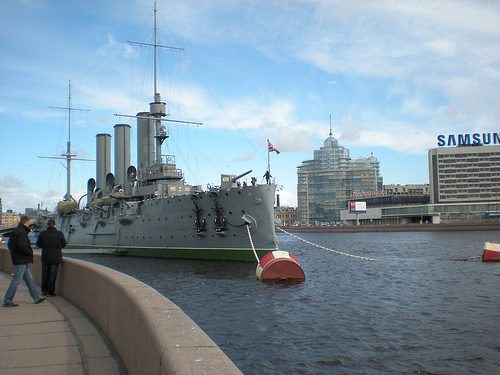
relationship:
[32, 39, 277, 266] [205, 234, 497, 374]
ship in water.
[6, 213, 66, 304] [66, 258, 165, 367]
men near wall.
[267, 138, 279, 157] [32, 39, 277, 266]
flag on ship.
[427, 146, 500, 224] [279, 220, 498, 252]
building near waterfront.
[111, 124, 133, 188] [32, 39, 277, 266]
smokestack on ship.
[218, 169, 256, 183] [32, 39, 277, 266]
turret on ship.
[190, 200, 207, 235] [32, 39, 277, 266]
anchor on ship.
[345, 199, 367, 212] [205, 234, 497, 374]
sign near water.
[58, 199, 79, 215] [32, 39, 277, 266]
lifeboats on ship.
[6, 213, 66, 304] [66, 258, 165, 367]
men next to wall.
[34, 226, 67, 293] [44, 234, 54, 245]
man in black.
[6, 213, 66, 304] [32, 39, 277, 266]
men looking at ship.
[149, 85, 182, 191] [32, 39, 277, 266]
tower at front of ship.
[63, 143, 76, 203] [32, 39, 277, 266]
tower at rear of ship.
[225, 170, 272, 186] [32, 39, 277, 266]
people at front of ship.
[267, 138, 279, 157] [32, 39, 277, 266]
flag at front of ship.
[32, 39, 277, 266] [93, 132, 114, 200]
ship has smokestacks.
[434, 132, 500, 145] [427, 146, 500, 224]
samsung on building.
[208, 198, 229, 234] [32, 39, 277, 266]
anchor on ship.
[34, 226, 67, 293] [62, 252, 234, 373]
person next to ledge.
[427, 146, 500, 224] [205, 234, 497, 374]
building next to water.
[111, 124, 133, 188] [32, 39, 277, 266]
smoke stacks on ship.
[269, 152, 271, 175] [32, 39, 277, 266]
pole on ship.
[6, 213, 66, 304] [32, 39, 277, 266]
people looking at a ship.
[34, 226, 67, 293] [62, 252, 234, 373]
man walking on pier.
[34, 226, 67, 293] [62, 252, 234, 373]
man standing on pier.